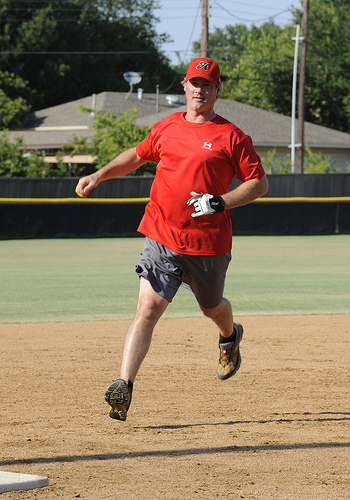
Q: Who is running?
A: A man.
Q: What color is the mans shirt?
A: Red.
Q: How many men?
A: 1.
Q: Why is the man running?
A: Playing.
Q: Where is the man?
A: The field.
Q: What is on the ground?
A: Dirt.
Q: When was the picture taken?
A: Daytime.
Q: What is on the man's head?
A: A hat.